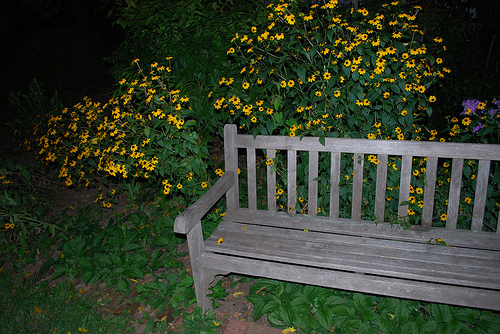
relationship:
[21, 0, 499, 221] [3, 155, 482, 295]
flower growing from ground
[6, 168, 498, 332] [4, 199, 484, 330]
weeds growing from ground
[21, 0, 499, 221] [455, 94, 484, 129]
flower growing from flowers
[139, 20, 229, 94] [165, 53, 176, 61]
bush behind yellow flower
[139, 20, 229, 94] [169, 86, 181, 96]
bush behind yellow flower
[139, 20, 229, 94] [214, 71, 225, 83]
bush behind yellow flower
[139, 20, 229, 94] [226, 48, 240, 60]
bush behind yellow flower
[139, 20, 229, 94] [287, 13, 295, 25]
bush behind yellow flower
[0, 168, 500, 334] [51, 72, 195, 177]
weeds next to flowers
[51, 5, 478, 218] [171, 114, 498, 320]
bouquet behind bench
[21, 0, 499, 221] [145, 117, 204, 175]
flower with leaves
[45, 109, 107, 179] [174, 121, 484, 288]
flower blooming through bench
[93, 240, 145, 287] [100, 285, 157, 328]
grass on ground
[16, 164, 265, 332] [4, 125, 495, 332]
dirt patches on ground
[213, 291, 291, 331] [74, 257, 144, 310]
dirt on ground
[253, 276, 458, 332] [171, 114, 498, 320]
leaves underneath a bench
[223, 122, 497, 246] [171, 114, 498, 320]
back rest of bench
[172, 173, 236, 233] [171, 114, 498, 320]
arm rest of bench